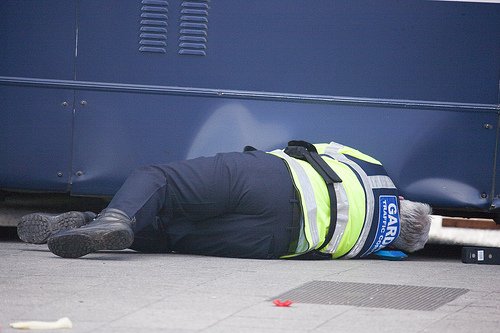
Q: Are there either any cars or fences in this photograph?
A: No, there are no fences or cars.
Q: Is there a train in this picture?
A: Yes, there is a train.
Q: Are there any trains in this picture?
A: Yes, there is a train.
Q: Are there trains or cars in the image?
A: Yes, there is a train.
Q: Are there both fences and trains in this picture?
A: No, there is a train but no fences.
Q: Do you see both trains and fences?
A: No, there is a train but no fences.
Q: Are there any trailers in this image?
A: No, there are no trailers.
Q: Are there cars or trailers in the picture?
A: No, there are no trailers or cars.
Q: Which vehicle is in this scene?
A: The vehicle is a train.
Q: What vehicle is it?
A: The vehicle is a train.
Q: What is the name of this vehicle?
A: This is a train.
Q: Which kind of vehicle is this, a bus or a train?
A: This is a train.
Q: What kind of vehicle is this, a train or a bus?
A: This is a train.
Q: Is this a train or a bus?
A: This is a train.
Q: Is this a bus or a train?
A: This is a train.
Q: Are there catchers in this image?
A: No, there are no catchers.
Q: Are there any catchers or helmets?
A: No, there are no catchers or helmets.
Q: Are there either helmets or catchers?
A: No, there are no catchers or helmets.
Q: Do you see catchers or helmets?
A: No, there are no catchers or helmets.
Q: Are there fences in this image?
A: No, there are no fences.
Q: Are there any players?
A: No, there are no players.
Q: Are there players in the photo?
A: No, there are no players.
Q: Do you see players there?
A: No, there are no players.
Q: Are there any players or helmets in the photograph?
A: No, there are no players or helmets.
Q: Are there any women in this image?
A: No, there are no women.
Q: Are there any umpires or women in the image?
A: No, there are no women or umpires.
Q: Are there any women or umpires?
A: No, there are no women or umpires.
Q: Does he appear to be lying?
A: Yes, the man is lying.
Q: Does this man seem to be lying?
A: Yes, the man is lying.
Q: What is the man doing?
A: The man is lying.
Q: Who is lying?
A: The man is lying.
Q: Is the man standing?
A: No, the man is lying.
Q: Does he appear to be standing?
A: No, the man is lying.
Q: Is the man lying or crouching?
A: The man is lying.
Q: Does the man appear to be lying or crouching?
A: The man is lying.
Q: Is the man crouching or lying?
A: The man is lying.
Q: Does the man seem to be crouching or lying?
A: The man is lying.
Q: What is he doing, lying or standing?
A: The man is lying.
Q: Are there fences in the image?
A: No, there are no fences.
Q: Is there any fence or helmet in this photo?
A: No, there are no fences or helmets.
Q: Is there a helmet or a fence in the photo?
A: No, there are no fences or helmets.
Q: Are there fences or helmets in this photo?
A: No, there are no fences or helmets.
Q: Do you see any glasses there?
A: No, there are no glasses.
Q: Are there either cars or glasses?
A: No, there are no glasses or cars.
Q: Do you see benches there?
A: No, there are no benches.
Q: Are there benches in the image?
A: No, there are no benches.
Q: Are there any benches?
A: No, there are no benches.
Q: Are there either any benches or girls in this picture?
A: No, there are no benches or girls.